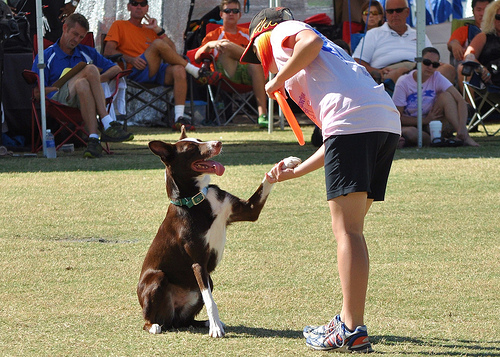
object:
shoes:
[304, 323, 372, 354]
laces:
[323, 316, 346, 346]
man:
[351, 0, 434, 86]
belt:
[385, 61, 416, 70]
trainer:
[239, 6, 404, 355]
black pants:
[321, 131, 402, 203]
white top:
[350, 21, 435, 71]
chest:
[194, 205, 229, 269]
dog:
[136, 125, 301, 339]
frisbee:
[272, 86, 307, 148]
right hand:
[262, 162, 297, 184]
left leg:
[301, 137, 370, 352]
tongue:
[201, 160, 226, 178]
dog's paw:
[270, 155, 304, 173]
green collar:
[167, 189, 207, 208]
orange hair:
[253, 30, 273, 76]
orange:
[280, 104, 294, 123]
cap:
[235, 7, 283, 64]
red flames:
[247, 13, 280, 38]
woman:
[392, 46, 483, 150]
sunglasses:
[422, 58, 441, 70]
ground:
[1, 125, 499, 356]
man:
[32, 12, 128, 161]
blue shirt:
[28, 41, 119, 100]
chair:
[22, 33, 134, 158]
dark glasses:
[383, 6, 410, 17]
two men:
[102, 1, 276, 130]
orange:
[122, 25, 151, 46]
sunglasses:
[222, 7, 242, 14]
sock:
[174, 104, 186, 122]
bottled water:
[42, 127, 58, 160]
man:
[101, 0, 217, 127]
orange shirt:
[104, 17, 152, 57]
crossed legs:
[51, 63, 133, 159]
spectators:
[28, 0, 499, 156]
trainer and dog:
[132, 8, 401, 352]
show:
[1, 0, 499, 356]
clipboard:
[50, 61, 88, 87]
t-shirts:
[103, 18, 166, 72]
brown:
[156, 240, 168, 261]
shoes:
[257, 113, 281, 129]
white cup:
[428, 120, 444, 146]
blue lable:
[45, 141, 55, 148]